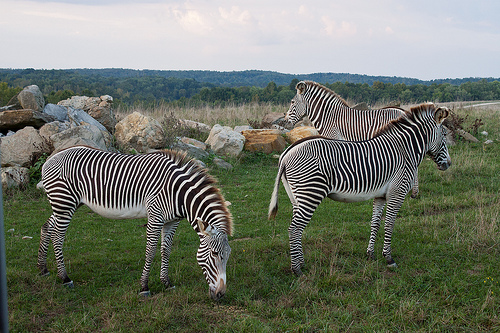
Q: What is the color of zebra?
A: Black and white.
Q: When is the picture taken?
A: Daytime.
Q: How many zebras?
A: 3.